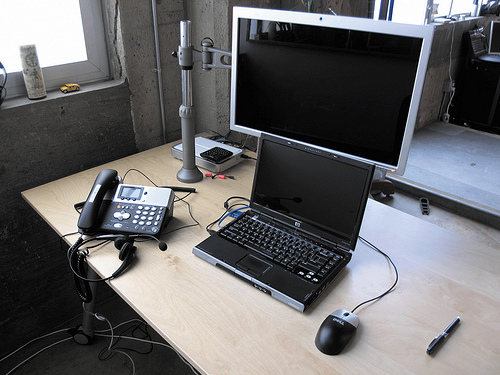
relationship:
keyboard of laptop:
[178, 200, 353, 319] [183, 123, 384, 328]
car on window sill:
[58, 80, 83, 94] [0, 78, 140, 361]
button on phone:
[145, 201, 161, 218] [58, 137, 178, 262]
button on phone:
[113, 222, 124, 228] [67, 153, 197, 275]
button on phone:
[120, 211, 130, 219] [74, 172, 201, 277]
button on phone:
[129, 213, 141, 219] [74, 167, 171, 234]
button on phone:
[112, 222, 121, 230] [74, 166, 175, 241]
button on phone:
[135, 205, 142, 210] [74, 166, 175, 241]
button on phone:
[140, 220, 147, 225] [74, 166, 175, 241]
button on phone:
[146, 215, 153, 220] [74, 166, 175, 241]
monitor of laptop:
[163, 4, 420, 181] [189, 132, 376, 313]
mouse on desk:
[313, 307, 357, 361] [15, 129, 495, 371]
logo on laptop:
[289, 218, 304, 231] [192, 127, 372, 309]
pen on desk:
[403, 300, 473, 364] [15, 129, 495, 371]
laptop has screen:
[192, 127, 372, 309] [252, 137, 367, 240]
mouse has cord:
[317, 234, 402, 355] [349, 234, 399, 313]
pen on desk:
[423, 317, 462, 356] [15, 129, 495, 371]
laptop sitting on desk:
[192, 127, 372, 309] [15, 129, 495, 371]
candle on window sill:
[16, 40, 56, 102] [0, 71, 125, 111]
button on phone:
[114, 221, 124, 229] [74, 167, 171, 234]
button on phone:
[139, 214, 146, 222] [74, 167, 171, 234]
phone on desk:
[75, 167, 175, 236] [74, 166, 314, 357]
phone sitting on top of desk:
[74, 166, 175, 241] [151, 266, 178, 286]